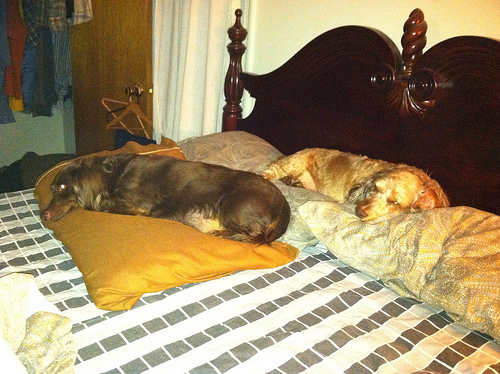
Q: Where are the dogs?
A: On the bed.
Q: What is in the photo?
A: Two dogs.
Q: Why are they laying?
A: Resting.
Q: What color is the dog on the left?
A: Brown.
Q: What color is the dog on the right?
A: Gold.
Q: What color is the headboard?
A: Brown.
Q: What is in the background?
A: Closet.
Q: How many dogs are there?
A: Two.